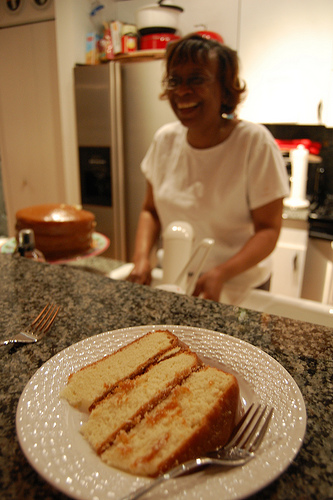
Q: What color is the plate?
A: White.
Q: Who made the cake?
A: Chef.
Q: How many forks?
A: Two.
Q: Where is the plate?
A: Counter.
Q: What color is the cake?
A: Brown.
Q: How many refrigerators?
A: One.